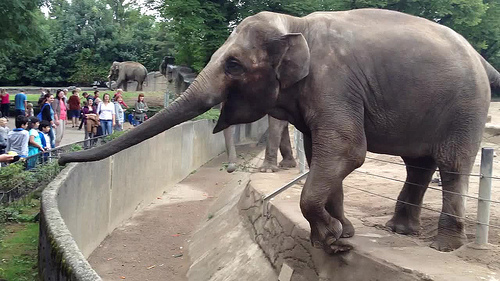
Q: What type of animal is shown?
A: Elephant.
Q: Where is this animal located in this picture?
A: Zoo.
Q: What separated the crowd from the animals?
A: Metal fence.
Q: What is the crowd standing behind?
A: Fence.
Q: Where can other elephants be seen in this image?
A: Background.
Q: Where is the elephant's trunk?
A: On edge of cement wall.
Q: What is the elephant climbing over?
A: Fence.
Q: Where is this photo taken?
A: Zoo.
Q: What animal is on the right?
A: Elephant.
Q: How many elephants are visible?
A: 2.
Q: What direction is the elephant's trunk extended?
A: Left.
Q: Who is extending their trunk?
A: Elephant.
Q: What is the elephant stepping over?
A: Fence.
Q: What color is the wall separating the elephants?
A: Gray.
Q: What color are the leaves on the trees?
A: Green.